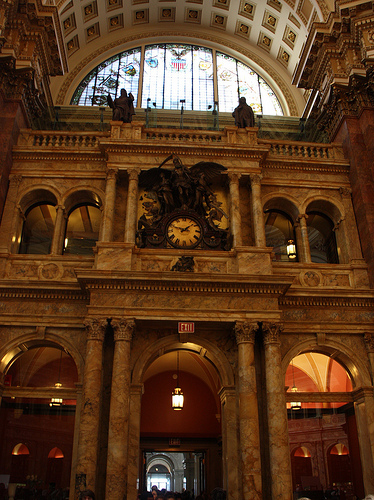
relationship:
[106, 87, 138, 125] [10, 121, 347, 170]
statue standing on balcony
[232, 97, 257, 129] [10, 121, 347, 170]
statue standing on balcony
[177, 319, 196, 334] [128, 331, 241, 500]
sign over archway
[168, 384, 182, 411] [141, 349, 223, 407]
lamp attached to ceiling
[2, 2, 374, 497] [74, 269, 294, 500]
building has an entrance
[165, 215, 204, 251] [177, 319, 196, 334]
clock over sign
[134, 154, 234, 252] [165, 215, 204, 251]
statue enclosing clock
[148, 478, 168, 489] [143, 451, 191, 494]
sunlight coming in through doors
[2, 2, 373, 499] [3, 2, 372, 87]
house has a roof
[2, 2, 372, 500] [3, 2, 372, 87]
palace has a roof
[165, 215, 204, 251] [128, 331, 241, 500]
clock over archway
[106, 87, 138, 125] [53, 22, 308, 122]
statue next to window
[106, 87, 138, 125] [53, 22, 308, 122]
statue near window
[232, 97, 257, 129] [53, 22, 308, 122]
statue near window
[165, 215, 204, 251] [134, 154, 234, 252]
clock surrounded by statue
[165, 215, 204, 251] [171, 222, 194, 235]
clock has black hands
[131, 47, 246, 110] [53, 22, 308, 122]
light coming through window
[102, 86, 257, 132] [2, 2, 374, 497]
sculptures are standing in building